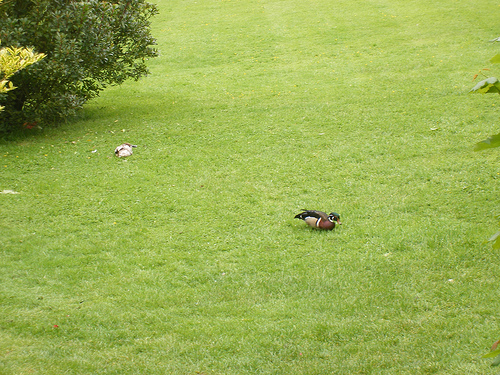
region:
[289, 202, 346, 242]
duck sitting on grass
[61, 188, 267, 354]
large field of natural grass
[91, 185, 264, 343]
bright green healthy grass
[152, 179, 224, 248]
thick bright green grass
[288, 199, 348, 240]
duck with black tail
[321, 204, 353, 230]
duck with green head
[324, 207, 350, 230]
duck with yellow beak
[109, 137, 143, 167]
duck looking for food to eat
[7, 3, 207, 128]
large dark green bush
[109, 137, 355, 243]
two duck on the grass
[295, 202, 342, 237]
Duck sitting on the green grass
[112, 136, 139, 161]
Duck laying on the grass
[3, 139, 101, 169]
Fallen leaves on the grass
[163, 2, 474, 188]
Large area of green grass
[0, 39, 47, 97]
Branch with yellow leaves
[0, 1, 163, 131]
Green leafy shrub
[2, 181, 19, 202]
Bare spot on the grass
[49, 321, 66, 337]
Red leaf on the grass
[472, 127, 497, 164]
Large green leaf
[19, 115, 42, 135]
Red leaves on bottom of green shrub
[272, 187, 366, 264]
duck sitting in grassy field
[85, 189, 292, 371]
ground covered in thick grass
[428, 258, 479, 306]
small grey rock laying in grass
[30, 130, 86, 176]
small white flower blooms in grassy field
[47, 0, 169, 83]
bush with dark green leaves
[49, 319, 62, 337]
small red leaf laying in grass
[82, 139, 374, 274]
two ducks sitting in grass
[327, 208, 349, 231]
green head of duck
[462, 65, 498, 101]
small green leaf on plant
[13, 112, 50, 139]
red flowers growing under bush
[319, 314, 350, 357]
part of a lawn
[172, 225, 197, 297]
edge of a lawn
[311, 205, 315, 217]
part of a bike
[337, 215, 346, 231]
beak of a bird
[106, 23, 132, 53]
part of a branch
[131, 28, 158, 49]
branches of a tree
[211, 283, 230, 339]
part of a field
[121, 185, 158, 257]
edge of a lawn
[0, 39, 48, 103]
the tree leaves are yellow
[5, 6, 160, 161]
this tree is dark green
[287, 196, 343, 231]
the duck is on the grass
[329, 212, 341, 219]
the duck head is green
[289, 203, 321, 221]
the duck's tail is dark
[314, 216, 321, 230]
a stripe on the duck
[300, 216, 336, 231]
the duck's body is brown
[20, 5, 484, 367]
the grass is yellow-green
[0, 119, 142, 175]
leaves on the ground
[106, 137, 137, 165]
a white object on the ground